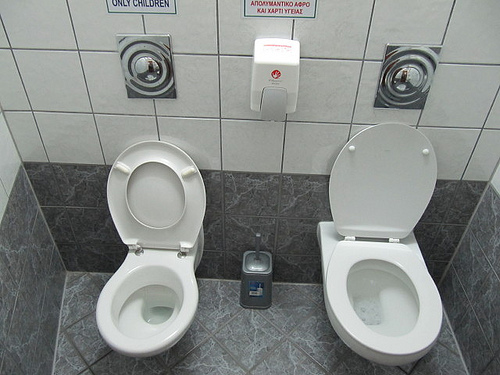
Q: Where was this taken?
A: Bathroom.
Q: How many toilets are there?
A: 2.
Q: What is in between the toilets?
A: Toilet brush.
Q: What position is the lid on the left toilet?
A: Up.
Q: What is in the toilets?
A: Water.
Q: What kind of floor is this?
A: Tile.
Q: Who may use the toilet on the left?
A: Children.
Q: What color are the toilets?
A: White.